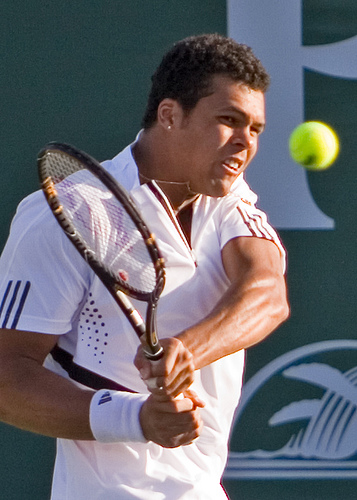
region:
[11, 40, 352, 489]
the man is playing tennis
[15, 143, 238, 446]
the man is holding a racket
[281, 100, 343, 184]
the ball is lime green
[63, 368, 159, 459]
the man is wearing a wrist band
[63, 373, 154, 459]
the wrist band is white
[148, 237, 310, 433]
the sun is on the man`s arm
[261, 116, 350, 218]
the ball is blurry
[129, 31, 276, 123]
the man`s hair is curly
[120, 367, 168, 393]
the man has a band aid on his finger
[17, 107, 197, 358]
the racket is black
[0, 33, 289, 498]
a man playing tennis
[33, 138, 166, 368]
a tennis racquet in the man's hands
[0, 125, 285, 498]
a white shirt on the tennis player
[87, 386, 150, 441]
a white wristband on the man's wrist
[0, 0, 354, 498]
a green wall behind the man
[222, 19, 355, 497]
white markings on the green wall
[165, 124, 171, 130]
small earring in the man's ear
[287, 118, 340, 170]
a yellow tennis ball in the air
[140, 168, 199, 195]
a necklace around the man's neck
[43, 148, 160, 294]
strings in the tennis racquet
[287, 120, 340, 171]
a tennis ball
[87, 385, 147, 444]
a white Adidas wrist band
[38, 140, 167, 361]
a tennis racket in a mans hand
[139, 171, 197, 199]
a gold chain necklace on a mans neck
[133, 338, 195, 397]
a mans hand holding a tennis racket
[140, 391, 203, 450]
a mans hand holding a tennis racket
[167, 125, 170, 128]
an earring in a mans ear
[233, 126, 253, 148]
a mans nose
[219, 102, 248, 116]
a mans eyebrow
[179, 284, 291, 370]
forearm muscles on left arm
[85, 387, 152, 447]
sweatband on right wrist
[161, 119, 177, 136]
earring on the player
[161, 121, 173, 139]
earring on the man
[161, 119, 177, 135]
earring on the person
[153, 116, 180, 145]
earring on the guy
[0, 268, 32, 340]
blue stripes on a sleeve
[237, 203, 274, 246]
red stripes on a sleeve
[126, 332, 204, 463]
two hands on the racquet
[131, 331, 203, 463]
two hands on the handle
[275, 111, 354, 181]
Green tennis ball flying through the air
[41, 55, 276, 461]
Man holding tennis racket with two hands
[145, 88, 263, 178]
Man wearing ear ring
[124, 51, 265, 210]
Man wearing necklace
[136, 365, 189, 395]
Man with band-aid on finger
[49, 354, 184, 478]
Wrist band on man's wrist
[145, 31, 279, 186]
Man with curly black hair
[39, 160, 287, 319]
Man wearing white shirt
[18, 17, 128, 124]
A green background behind tennis player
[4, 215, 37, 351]
Blue trim on shirt sleeve